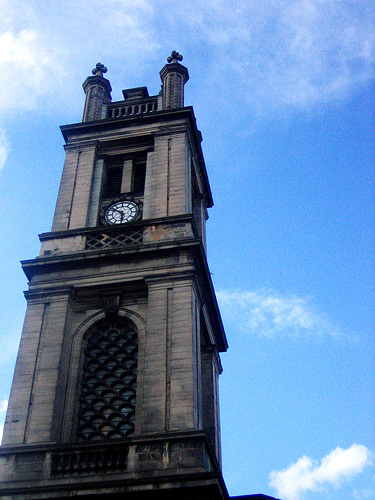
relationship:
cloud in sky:
[0, 0, 375, 499] [2, 1, 372, 497]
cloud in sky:
[0, 0, 375, 499] [243, 159, 342, 258]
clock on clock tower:
[100, 196, 143, 227] [0, 49, 229, 498]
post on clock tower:
[160, 48, 193, 110] [0, 49, 229, 498]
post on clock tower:
[78, 63, 116, 119] [0, 49, 229, 498]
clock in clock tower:
[100, 196, 143, 227] [0, 49, 229, 498]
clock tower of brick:
[0, 49, 229, 498] [173, 304, 190, 308]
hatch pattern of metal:
[82, 224, 143, 253] [83, 227, 146, 250]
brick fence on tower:
[103, 98, 161, 115] [16, 49, 245, 496]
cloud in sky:
[0, 0, 375, 499] [284, 160, 354, 258]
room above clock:
[99, 151, 148, 199] [101, 196, 139, 224]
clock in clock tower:
[101, 196, 139, 224] [0, 49, 229, 498]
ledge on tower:
[20, 224, 203, 274] [61, 53, 221, 254]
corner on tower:
[179, 74, 210, 254] [61, 53, 221, 254]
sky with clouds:
[2, 1, 372, 497] [270, 435, 368, 500]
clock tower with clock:
[0, 49, 229, 498] [100, 196, 143, 227]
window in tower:
[77, 317, 143, 445] [20, 49, 240, 435]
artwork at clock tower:
[85, 58, 115, 78] [0, 49, 229, 498]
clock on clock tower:
[102, 199, 138, 224] [0, 49, 229, 498]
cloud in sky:
[1, 26, 38, 75] [45, 8, 363, 47]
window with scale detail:
[58, 302, 145, 466] [82, 324, 135, 446]